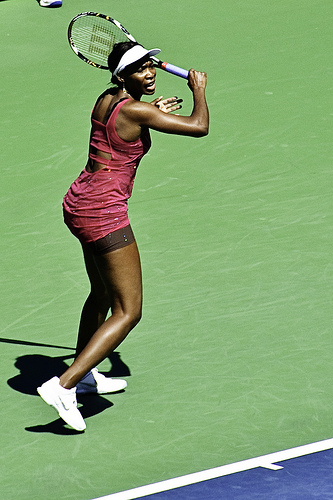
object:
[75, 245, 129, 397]
leg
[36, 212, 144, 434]
leg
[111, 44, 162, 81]
cap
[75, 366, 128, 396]
white shoe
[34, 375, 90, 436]
shoes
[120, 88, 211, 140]
bent arm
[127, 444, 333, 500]
blue ground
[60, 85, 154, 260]
outfit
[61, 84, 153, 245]
top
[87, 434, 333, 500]
white line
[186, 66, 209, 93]
hand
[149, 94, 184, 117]
hand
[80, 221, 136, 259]
bottom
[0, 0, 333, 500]
turf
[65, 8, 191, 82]
tennis racket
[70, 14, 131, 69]
net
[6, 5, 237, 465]
tennis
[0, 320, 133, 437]
shadow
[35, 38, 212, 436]
she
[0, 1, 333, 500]
court